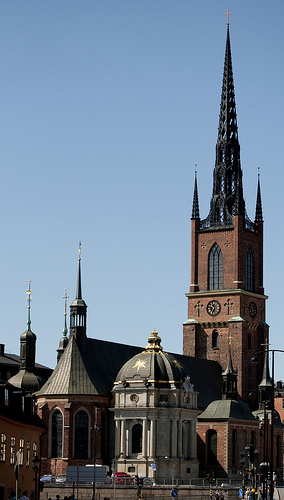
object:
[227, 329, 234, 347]
crosses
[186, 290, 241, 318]
wall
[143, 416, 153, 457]
columns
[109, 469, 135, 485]
car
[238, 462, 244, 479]
part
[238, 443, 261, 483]
light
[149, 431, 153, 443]
part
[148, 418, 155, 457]
pillar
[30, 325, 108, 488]
building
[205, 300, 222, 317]
clock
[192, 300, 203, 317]
cross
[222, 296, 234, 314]
cross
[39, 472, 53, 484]
car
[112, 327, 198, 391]
dome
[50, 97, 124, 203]
sky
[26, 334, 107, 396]
roof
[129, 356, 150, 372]
star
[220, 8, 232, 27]
cross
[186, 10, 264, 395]
building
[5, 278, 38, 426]
building